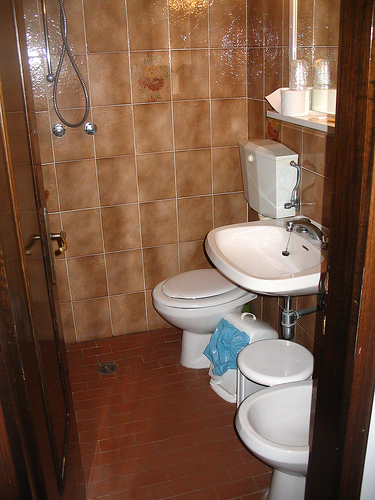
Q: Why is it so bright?
A: Lights are on.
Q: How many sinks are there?
A: One.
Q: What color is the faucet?
A: Silver.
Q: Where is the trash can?
A: Under the sink.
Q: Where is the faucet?
A: The sink.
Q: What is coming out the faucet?
A: Water.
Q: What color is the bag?
A: Blue.